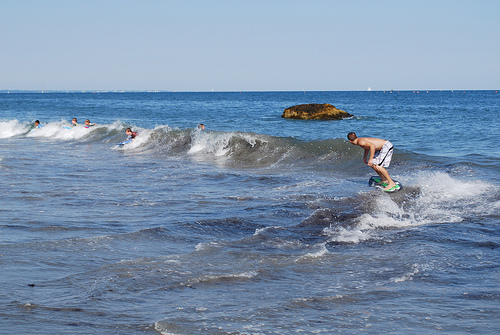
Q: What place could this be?
A: It is a sea.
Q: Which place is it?
A: It is a sea.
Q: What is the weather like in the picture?
A: It is clear.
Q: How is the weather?
A: It is clear.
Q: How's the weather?
A: It is clear.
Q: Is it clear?
A: Yes, it is clear.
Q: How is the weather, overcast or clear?
A: It is clear.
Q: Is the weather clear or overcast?
A: It is clear.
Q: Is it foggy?
A: No, it is clear.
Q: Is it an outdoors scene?
A: Yes, it is outdoors.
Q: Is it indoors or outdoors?
A: It is outdoors.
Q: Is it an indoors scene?
A: No, it is outdoors.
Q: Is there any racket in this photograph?
A: No, there are no rackets.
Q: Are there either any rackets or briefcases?
A: No, there are no rackets or briefcases.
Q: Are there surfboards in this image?
A: Yes, there is a surfboard.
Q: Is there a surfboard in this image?
A: Yes, there is a surfboard.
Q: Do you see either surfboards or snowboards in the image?
A: Yes, there is a surfboard.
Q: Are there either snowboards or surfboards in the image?
A: Yes, there is a surfboard.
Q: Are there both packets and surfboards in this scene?
A: No, there is a surfboard but no packets.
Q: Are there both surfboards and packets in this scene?
A: No, there is a surfboard but no packets.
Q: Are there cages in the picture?
A: No, there are no cages.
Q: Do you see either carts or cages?
A: No, there are no cages or carts.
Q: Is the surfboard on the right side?
A: Yes, the surfboard is on the right of the image.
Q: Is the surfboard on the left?
A: No, the surfboard is on the right of the image.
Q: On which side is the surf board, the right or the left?
A: The surf board is on the right of the image.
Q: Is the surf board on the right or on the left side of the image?
A: The surf board is on the right of the image.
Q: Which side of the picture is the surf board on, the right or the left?
A: The surf board is on the right of the image.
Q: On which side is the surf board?
A: The surf board is on the right of the image.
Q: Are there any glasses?
A: No, there are no glasses.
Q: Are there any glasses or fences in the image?
A: No, there are no glasses or fences.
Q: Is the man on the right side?
A: Yes, the man is on the right of the image.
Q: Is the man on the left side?
A: No, the man is on the right of the image.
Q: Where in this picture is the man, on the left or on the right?
A: The man is on the right of the image.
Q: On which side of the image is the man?
A: The man is on the right of the image.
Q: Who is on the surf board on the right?
A: The man is on the surfboard.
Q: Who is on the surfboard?
A: The man is on the surfboard.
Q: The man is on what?
A: The man is on the surfboard.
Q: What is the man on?
A: The man is on the surfboard.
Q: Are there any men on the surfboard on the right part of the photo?
A: Yes, there is a man on the surfboard.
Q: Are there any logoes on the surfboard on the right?
A: No, there is a man on the surf board.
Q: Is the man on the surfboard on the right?
A: Yes, the man is on the surfboard.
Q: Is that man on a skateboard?
A: No, the man is on the surfboard.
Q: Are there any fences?
A: No, there are no fences.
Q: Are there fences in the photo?
A: No, there are no fences.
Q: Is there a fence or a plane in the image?
A: No, there are no fences or airplanes.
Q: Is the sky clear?
A: Yes, the sky is clear.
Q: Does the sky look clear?
A: Yes, the sky is clear.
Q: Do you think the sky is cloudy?
A: No, the sky is clear.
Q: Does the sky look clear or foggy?
A: The sky is clear.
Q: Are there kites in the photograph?
A: No, there are no kites.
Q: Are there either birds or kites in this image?
A: No, there are no kites or birds.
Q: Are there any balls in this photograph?
A: No, there are no balls.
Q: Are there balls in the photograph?
A: No, there are no balls.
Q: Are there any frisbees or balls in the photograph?
A: No, there are no balls or frisbees.